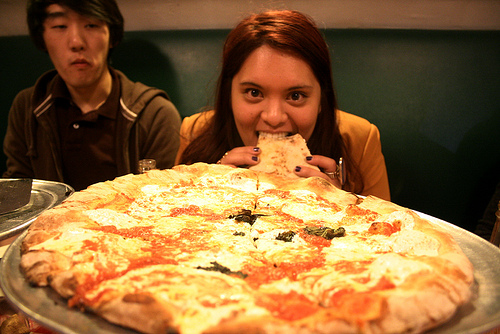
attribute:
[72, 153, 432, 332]
pizza — large, white, cooked, big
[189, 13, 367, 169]
girl — eating, white, sitting, young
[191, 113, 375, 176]
shirt — yellow, brown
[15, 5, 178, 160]
boy — asian, sitting, brown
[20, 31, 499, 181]
booth — green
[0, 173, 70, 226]
tray — empty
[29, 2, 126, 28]
hair — black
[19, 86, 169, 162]
shirt — brown